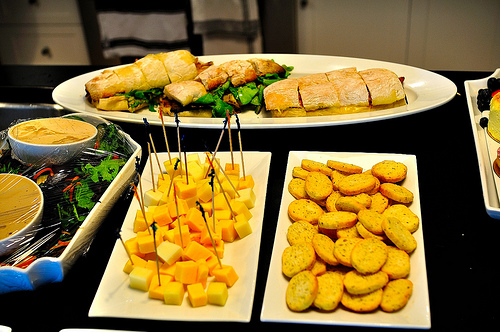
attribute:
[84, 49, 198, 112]
bread — round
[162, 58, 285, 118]
bread — round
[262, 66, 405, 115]
bread — round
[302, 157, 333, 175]
bread — round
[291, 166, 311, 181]
bread — round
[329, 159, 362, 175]
bread — round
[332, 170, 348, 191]
bread — round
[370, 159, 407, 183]
bread — round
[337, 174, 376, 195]
bread — round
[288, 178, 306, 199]
bread — round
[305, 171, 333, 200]
bread — round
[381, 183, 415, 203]
bread — round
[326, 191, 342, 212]
bread — round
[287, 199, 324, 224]
bread — round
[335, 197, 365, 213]
bread — round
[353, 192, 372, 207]
bread — round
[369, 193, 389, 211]
bread — round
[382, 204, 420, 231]
bread — round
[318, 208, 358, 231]
bread — round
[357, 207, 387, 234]
bread — round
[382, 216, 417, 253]
bread — round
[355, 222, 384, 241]
bread — round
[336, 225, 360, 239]
bread — round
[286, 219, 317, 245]
bread — round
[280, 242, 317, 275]
bread — round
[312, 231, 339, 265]
bread — round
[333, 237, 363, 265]
bread — round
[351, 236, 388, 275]
bread — round, crusty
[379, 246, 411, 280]
bread — round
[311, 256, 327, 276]
bread — round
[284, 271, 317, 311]
bread — round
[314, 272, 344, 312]
bread — round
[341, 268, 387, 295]
bread — round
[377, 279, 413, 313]
bread — round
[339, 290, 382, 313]
bread — round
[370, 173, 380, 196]
bread — round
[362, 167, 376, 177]
bread — round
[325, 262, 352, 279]
bread — round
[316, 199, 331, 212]
bread — round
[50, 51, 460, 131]
plate — white, large, oblong, oval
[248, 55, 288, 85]
sandwich segment — sliced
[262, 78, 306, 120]
sandwich segment — sliced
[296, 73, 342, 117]
sandwich segment — sliced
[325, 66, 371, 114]
sandwich segment — sliced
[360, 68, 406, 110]
sandwich segment — sliced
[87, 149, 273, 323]
plate — white, large, oblong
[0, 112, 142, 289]
plate — white, large, oblong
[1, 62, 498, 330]
table — black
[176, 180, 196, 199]
cheese cube — cubed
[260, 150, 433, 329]
plate — white, large, oblong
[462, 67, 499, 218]
plate — white, large, oblong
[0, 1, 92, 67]
cabinet — white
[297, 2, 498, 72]
cabinet — white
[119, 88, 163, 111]
leaves — green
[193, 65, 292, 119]
leaves — green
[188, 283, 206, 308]
cheese cube — cubed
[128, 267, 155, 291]
cheese cube — cubed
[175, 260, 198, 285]
cheese cube — cubed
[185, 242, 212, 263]
cheese cube — cubed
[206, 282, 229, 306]
cheese cube — cubed